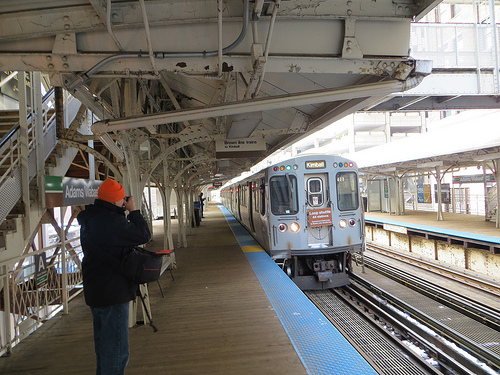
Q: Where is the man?
A: On the platform.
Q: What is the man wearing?
A: Red beanie.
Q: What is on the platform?
A: Set of Stairs.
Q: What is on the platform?
A: Blue line.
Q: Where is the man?
A: On a platform.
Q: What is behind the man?
A: Stairs.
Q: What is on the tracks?
A: A train.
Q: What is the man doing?
A: Taking a picture.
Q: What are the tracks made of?
A: Steel.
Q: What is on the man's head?
A: An orange hat.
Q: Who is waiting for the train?
A: The man with the orange hat.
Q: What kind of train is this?
A: A passenger train.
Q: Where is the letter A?
A: Behind the man.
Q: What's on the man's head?
A: Orange beanie.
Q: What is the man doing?
A: Taking a picture.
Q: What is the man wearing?
A: A coat.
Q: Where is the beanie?
A: On the man's head.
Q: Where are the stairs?
A: To the left.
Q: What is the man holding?
A: A camera.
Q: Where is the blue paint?
A: On the platform.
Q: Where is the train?
A: In the station.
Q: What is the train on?
A: Tracks.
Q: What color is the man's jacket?
A: Blue.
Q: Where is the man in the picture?
A: A train station.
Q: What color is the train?
A: Gray.